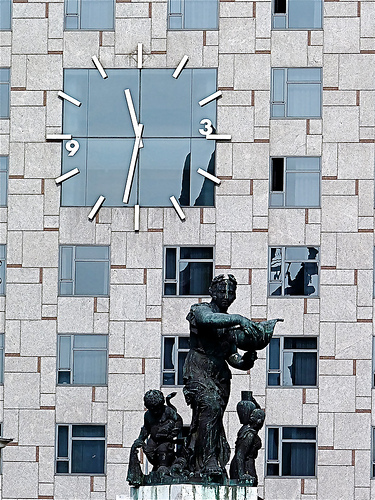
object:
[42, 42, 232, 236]
clock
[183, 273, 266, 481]
statue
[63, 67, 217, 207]
reflection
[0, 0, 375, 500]
hotel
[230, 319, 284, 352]
bowl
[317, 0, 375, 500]
walls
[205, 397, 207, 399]
stain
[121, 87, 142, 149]
hands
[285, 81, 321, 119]
window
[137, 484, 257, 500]
base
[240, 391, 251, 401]
vase